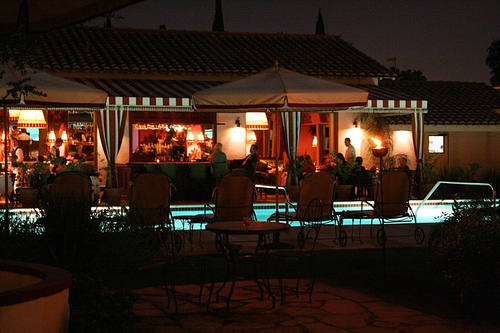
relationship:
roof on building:
[37, 28, 394, 81] [2, 78, 418, 192]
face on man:
[343, 139, 350, 145] [339, 136, 359, 164]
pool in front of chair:
[410, 187, 484, 224] [124, 170, 182, 221]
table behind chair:
[209, 215, 294, 310] [124, 170, 182, 221]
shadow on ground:
[328, 295, 393, 333] [313, 281, 429, 332]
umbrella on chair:
[184, 56, 372, 125] [193, 170, 265, 227]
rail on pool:
[417, 178, 500, 214] [410, 187, 484, 224]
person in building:
[244, 143, 265, 173] [2, 78, 418, 192]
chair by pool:
[124, 170, 182, 221] [410, 187, 484, 224]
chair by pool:
[348, 167, 428, 240] [410, 187, 484, 224]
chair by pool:
[284, 165, 352, 241] [410, 187, 484, 224]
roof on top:
[37, 28, 394, 81] [97, 29, 333, 48]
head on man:
[246, 143, 261, 156] [244, 143, 265, 173]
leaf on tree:
[407, 67, 422, 74] [389, 67, 428, 81]